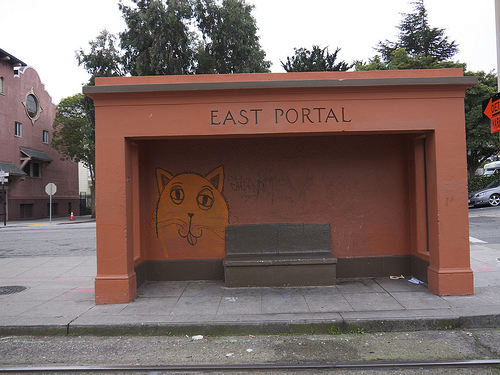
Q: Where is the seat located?
A: In the middle.